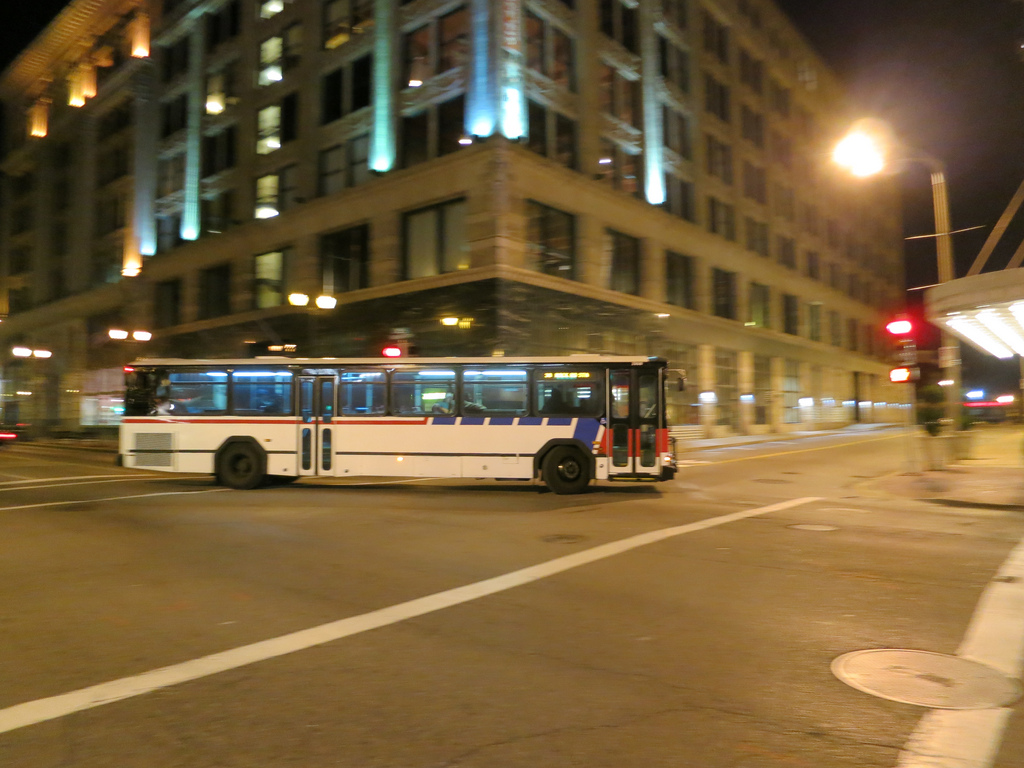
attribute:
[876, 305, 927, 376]
light — red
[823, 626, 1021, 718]
pothole — round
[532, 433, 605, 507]
rubber tire — black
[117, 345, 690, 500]
bus — long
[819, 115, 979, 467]
street light — on